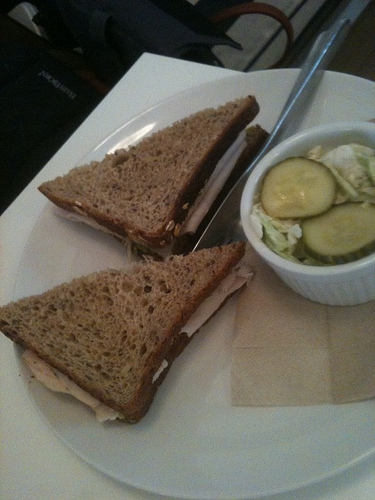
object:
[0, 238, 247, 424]
bread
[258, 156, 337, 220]
pickle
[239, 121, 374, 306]
ramekin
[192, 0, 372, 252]
knife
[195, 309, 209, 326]
meat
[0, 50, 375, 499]
plate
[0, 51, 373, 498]
mat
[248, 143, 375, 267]
coleslaw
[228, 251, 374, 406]
napkin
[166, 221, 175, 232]
oat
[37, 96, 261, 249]
bread